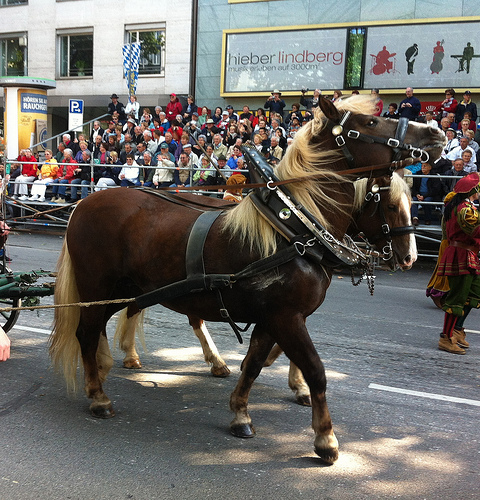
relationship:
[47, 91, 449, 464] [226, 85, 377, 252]
horse has blond mane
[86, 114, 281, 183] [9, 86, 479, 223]
spectators in crowd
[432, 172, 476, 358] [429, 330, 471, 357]
man wearing construction boots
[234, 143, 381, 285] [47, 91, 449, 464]
bridle on horse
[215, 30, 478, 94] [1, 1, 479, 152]
advertisement on building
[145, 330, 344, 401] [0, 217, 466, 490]
sunlight on asphalt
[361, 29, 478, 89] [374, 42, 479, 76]
picture of musicians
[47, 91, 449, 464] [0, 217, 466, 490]
horse on asphalt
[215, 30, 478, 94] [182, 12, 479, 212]
advertisement for a store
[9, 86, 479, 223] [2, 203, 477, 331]
crowd watching a parade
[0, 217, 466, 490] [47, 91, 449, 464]
asphalt under horse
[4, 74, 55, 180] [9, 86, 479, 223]
advertisement tower next to crowd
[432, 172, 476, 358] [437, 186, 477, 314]
man in a costume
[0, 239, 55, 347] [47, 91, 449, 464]
cart attached to horse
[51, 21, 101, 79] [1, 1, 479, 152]
window on a building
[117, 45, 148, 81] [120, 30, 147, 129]
flag hanging on a pole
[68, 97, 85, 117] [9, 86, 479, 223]
parking sign by crowd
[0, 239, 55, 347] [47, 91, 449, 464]
cart attached to a horse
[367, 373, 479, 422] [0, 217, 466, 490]
line on asphalt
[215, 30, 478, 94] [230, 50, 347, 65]
advertisement says hieber lindberg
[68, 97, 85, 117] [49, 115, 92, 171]
parking sign tells where to park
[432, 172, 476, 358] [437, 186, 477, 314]
man wearing a costume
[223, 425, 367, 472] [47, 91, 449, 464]
hooves on a horse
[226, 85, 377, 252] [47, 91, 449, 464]
blond mane of a horse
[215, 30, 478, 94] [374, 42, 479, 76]
advertisement showing musicians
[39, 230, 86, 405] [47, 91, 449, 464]
tail of a horse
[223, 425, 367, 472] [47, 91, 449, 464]
hooves of a horse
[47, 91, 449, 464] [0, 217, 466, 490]
horse walking on asphalt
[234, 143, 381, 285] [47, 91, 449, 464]
bridle on back of horse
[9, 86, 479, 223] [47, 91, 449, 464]
crowd watching horse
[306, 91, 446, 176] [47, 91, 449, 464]
head on a horse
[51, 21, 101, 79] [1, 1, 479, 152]
window of a building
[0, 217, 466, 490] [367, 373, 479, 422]
asphalt has line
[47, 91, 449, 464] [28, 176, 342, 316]
horse has reigns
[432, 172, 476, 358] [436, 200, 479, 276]
man wearing red coat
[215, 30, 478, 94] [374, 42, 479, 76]
advertisement has musicians